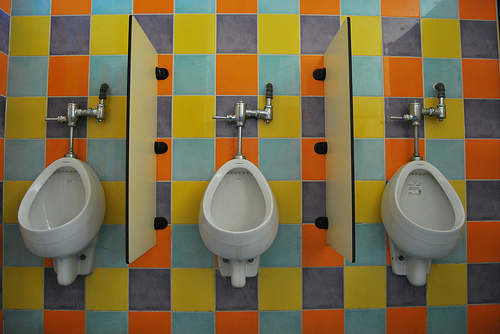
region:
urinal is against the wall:
[194, 81, 294, 290]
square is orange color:
[216, 50, 259, 95]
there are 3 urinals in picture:
[12, 76, 499, 253]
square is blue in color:
[258, 56, 303, 96]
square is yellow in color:
[253, 265, 308, 310]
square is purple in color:
[125, 265, 172, 312]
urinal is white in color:
[197, 82, 283, 284]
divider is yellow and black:
[309, 17, 368, 264]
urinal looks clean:
[378, 77, 468, 292]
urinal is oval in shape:
[380, 78, 476, 292]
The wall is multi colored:
[155, 15, 339, 71]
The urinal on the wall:
[193, 92, 281, 296]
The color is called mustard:
[171, 10, 217, 51]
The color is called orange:
[213, 310, 258, 331]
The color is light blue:
[171, 228, 213, 266]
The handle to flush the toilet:
[206, 106, 235, 126]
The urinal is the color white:
[196, 160, 278, 262]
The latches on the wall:
[308, 63, 333, 237]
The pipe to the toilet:
[230, 96, 275, 156]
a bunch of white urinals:
[10, 15, 476, 295]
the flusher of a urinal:
[39, 108, 64, 128]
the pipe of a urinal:
[55, 93, 85, 161]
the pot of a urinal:
[26, 148, 103, 257]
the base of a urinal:
[45, 255, 98, 286]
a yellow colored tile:
[83, 265, 130, 310]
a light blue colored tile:
[85, 226, 130, 264]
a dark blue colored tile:
[132, 265, 169, 314]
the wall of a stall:
[97, 15, 175, 240]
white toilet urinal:
[11, 73, 122, 289]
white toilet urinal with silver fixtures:
[11, 68, 114, 300]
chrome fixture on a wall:
[36, 82, 116, 142]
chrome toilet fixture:
[29, 73, 121, 141]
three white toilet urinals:
[9, 41, 483, 301]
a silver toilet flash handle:
[24, 85, 91, 139]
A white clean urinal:
[372, 148, 476, 288]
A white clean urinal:
[201, 146, 293, 267]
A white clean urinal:
[2, 155, 144, 274]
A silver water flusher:
[43, 85, 109, 142]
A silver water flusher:
[207, 81, 278, 158]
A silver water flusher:
[380, 85, 474, 162]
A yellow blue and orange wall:
[168, 13, 318, 52]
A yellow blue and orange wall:
[11, 3, 106, 81]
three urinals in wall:
[16, 148, 476, 294]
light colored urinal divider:
[121, 12, 165, 268]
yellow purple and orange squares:
[3, 1, 494, 325]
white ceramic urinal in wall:
[201, 150, 283, 297]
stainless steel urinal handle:
[199, 77, 291, 163]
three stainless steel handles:
[29, 67, 454, 155]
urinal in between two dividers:
[111, 4, 368, 289]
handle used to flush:
[36, 107, 66, 129]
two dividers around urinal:
[116, 9, 364, 294]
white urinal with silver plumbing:
[186, 85, 284, 291]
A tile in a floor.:
[158, 269, 216, 313]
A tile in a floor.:
[215, 265, 259, 318]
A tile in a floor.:
[255, 265, 304, 312]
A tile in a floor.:
[261, 222, 301, 266]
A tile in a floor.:
[297, 224, 345, 265]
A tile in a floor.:
[251, 137, 303, 180]